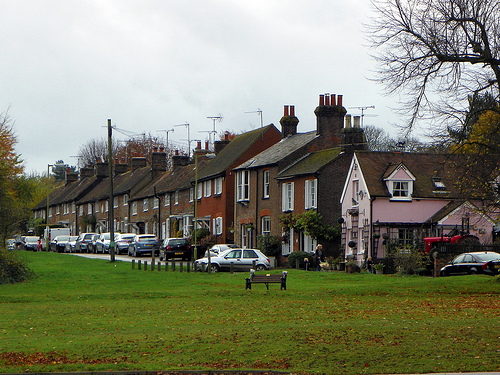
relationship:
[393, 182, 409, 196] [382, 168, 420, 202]
curtains hanging in window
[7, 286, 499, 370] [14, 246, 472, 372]
grass in field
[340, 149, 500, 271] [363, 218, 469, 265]
building has dormers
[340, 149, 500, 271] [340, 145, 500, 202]
building with a roof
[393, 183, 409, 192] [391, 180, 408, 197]
curtains are on a window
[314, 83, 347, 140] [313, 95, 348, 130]
chimney has roof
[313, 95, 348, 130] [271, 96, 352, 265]
roof on building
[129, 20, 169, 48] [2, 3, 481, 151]
clouds in sky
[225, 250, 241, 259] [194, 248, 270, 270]
car window of car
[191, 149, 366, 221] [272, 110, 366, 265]
windows of houses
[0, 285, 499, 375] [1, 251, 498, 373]
brown leaves on grass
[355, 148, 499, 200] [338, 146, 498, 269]
roof of house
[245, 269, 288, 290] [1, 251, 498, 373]
bench in grass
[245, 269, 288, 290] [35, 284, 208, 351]
bench in field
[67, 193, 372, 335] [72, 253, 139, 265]
cars parked next to curb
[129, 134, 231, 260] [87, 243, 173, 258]
building on street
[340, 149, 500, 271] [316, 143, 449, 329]
building with trim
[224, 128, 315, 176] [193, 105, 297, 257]
roof on building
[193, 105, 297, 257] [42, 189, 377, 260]
building in a row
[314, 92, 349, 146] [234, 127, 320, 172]
chimney on roof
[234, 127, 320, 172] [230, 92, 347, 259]
roof of a building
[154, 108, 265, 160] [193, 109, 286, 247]
antenna on building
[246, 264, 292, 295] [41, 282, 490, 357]
bench on field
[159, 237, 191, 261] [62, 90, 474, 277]
car in front of buildings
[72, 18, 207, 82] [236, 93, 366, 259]
sky above building